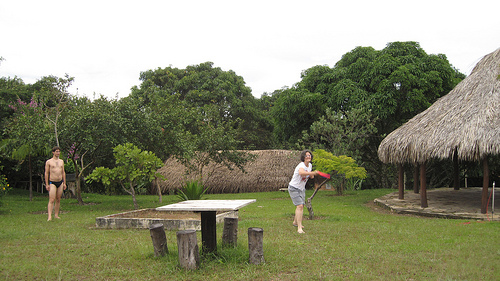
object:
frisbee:
[316, 170, 331, 179]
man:
[44, 145, 68, 221]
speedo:
[48, 180, 65, 188]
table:
[155, 198, 257, 260]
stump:
[247, 226, 265, 264]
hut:
[377, 48, 500, 215]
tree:
[83, 141, 166, 210]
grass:
[119, 195, 159, 207]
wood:
[418, 158, 428, 209]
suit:
[287, 161, 313, 206]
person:
[287, 150, 331, 234]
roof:
[147, 149, 312, 193]